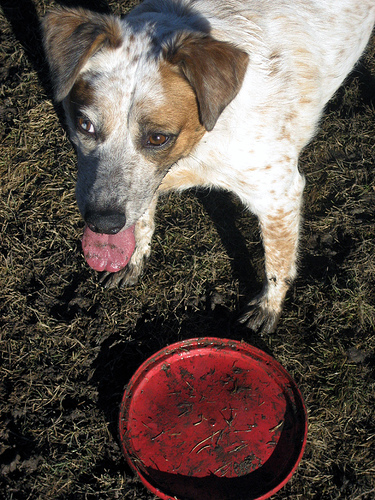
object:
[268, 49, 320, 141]
spots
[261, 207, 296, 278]
spots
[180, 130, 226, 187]
fur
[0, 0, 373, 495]
mud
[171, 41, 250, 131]
ear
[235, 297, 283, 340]
dog's paw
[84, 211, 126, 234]
nose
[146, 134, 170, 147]
brown eye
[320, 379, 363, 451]
grass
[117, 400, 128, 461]
edge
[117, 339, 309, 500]
floater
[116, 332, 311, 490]
frisbee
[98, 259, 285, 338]
yes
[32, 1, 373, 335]
yes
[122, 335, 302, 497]
lid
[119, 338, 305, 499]
dirty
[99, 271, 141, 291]
paws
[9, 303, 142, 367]
ground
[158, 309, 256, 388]
plastic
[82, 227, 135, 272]
tongue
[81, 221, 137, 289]
mouth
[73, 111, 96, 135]
eye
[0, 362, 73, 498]
grass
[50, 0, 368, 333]
dog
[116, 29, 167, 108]
fur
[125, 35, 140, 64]
spots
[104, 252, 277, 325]
paws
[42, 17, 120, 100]
ear